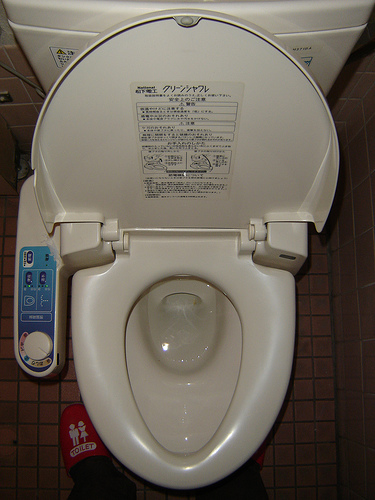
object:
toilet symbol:
[65, 420, 96, 459]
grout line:
[0, 399, 82, 402]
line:
[304, 280, 322, 428]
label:
[50, 46, 76, 73]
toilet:
[0, 0, 375, 500]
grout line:
[307, 299, 315, 324]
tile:
[309, 353, 352, 455]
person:
[54, 400, 269, 500]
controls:
[16, 245, 57, 373]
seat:
[68, 230, 295, 490]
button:
[19, 328, 53, 361]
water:
[167, 315, 191, 340]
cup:
[55, 398, 133, 500]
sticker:
[132, 80, 245, 198]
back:
[26, 8, 342, 243]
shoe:
[53, 400, 123, 498]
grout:
[314, 395, 335, 400]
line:
[330, 255, 346, 500]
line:
[0, 441, 59, 449]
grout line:
[325, 229, 343, 498]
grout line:
[308, 252, 329, 257]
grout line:
[295, 272, 333, 278]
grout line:
[296, 313, 332, 319]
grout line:
[291, 378, 337, 382]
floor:
[3, 208, 375, 500]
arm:
[13, 175, 63, 382]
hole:
[163, 294, 203, 313]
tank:
[0, 0, 373, 117]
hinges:
[100, 216, 267, 256]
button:
[24, 252, 30, 262]